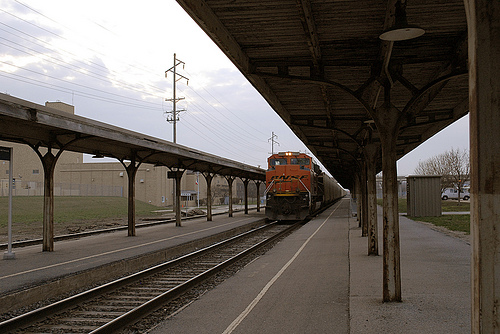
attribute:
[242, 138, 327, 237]
train — orange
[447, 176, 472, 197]
car — white, parked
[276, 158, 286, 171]
paper — white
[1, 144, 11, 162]
flag — white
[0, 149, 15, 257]
pole — flag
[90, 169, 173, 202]
building — tan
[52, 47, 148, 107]
line — power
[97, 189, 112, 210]
grass — green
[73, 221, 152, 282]
line — white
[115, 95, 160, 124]
sky — blue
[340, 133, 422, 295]
pillar — holding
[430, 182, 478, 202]
van — white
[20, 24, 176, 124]
wire — connected